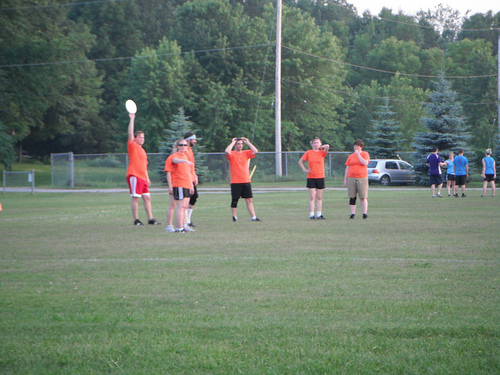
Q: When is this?
A: Daytime.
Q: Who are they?
A: Players.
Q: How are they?
A: Standing.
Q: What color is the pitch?
A: Green.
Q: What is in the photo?
A: Trees.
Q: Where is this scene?
A: On a ball field.